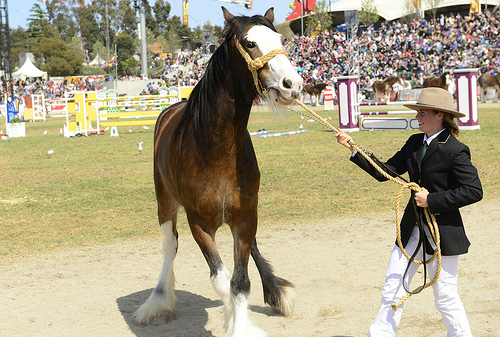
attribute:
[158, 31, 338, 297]
horse — brown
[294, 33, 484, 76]
spectators — section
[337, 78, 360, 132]
fence — red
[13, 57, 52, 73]
tent — pointed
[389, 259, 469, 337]
pants — white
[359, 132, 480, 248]
jacket — black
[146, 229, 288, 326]
legs — brown white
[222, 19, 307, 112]
face — white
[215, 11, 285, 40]
ears — pointy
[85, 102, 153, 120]
horse jump — red, yellow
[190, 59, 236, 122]
mane — black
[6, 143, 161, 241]
arena — grassy